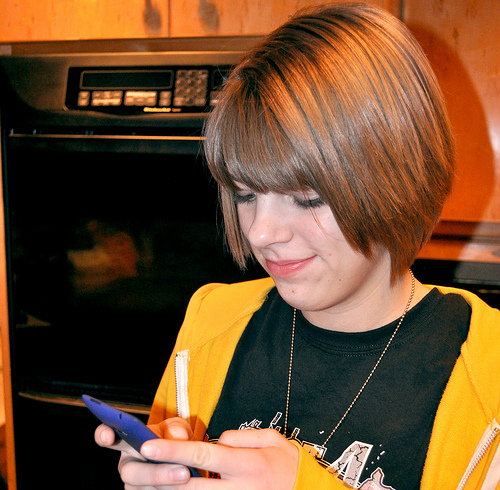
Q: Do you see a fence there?
A: No, there are no fences.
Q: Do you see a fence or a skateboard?
A: No, there are no fences or skateboards.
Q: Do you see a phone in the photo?
A: Yes, there is a phone.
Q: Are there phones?
A: Yes, there is a phone.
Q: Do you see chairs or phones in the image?
A: Yes, there is a phone.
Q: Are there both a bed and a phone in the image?
A: No, there is a phone but no beds.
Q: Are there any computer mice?
A: No, there are no computer mice.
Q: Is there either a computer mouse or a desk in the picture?
A: No, there are no computer mice or desks.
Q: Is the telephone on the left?
A: Yes, the telephone is on the left of the image.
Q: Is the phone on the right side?
A: No, the phone is on the left of the image.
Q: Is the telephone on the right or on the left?
A: The telephone is on the left of the image.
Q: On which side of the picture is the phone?
A: The phone is on the left of the image.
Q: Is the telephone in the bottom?
A: Yes, the telephone is in the bottom of the image.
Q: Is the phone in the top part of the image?
A: No, the phone is in the bottom of the image.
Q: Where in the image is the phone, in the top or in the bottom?
A: The phone is in the bottom of the image.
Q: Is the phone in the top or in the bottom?
A: The phone is in the bottom of the image.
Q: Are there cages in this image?
A: No, there are no cages.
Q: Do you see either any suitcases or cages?
A: No, there are no cages or suitcases.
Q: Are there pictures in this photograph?
A: No, there are no pictures.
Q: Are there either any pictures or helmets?
A: No, there are no pictures or helmets.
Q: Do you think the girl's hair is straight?
A: Yes, the hair is straight.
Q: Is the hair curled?
A: No, the hair is straight.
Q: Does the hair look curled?
A: No, the hair is straight.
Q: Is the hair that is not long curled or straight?
A: The hair is straight.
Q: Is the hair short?
A: Yes, the hair is short.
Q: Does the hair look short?
A: Yes, the hair is short.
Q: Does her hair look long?
A: No, the hair is short.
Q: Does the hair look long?
A: No, the hair is short.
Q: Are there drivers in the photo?
A: No, there are no drivers.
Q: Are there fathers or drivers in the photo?
A: No, there are no drivers or fathers.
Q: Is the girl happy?
A: Yes, the girl is happy.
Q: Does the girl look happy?
A: Yes, the girl is happy.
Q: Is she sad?
A: No, the girl is happy.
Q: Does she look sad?
A: No, the girl is happy.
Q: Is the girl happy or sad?
A: The girl is happy.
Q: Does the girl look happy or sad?
A: The girl is happy.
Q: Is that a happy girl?
A: Yes, that is a happy girl.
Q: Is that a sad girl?
A: No, that is a happy girl.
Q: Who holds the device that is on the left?
A: The girl holds the telephone.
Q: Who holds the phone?
A: The girl holds the telephone.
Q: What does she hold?
A: The girl holds the phone.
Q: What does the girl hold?
A: The girl holds the phone.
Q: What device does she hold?
A: The girl holds the phone.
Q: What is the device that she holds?
A: The device is a phone.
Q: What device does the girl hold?
A: The girl holds the phone.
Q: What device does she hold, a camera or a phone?
A: The girl holds a phone.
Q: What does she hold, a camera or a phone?
A: The girl holds a phone.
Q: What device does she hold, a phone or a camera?
A: The girl holds a phone.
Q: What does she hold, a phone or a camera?
A: The girl holds a phone.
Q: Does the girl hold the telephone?
A: Yes, the girl holds the telephone.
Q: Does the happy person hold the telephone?
A: Yes, the girl holds the telephone.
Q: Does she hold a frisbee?
A: No, the girl holds the telephone.